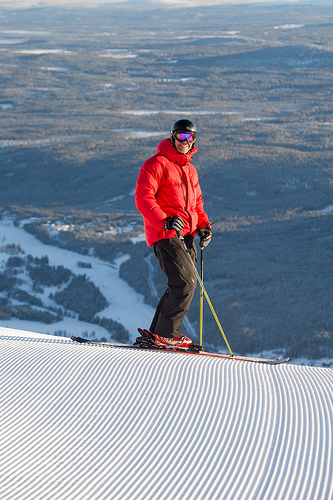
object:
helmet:
[170, 118, 197, 147]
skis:
[70, 335, 291, 366]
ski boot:
[143, 328, 194, 351]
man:
[133, 118, 213, 352]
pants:
[149, 237, 198, 341]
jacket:
[135, 138, 211, 247]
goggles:
[170, 130, 198, 145]